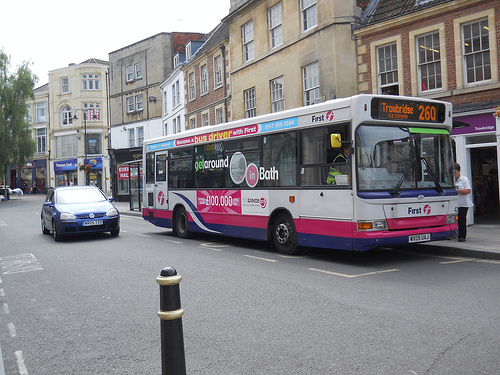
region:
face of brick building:
[365, 2, 497, 118]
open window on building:
[373, 40, 398, 97]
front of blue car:
[43, 183, 118, 240]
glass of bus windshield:
[357, 126, 454, 193]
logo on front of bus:
[406, 203, 431, 215]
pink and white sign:
[195, 188, 241, 213]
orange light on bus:
[356, 219, 372, 231]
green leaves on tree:
[0, 50, 40, 185]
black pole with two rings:
[158, 266, 185, 373]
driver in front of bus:
[323, 144, 355, 186]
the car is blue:
[30, 148, 237, 212]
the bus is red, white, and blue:
[121, 127, 493, 302]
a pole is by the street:
[120, 265, 222, 351]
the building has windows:
[194, 25, 328, 90]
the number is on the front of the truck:
[372, 88, 487, 118]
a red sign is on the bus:
[190, 192, 262, 213]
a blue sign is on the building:
[50, 160, 98, 170]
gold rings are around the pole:
[137, 258, 210, 361]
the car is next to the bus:
[27, 140, 395, 368]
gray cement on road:
[43, 267, 78, 288]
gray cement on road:
[227, 300, 267, 327]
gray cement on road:
[282, 335, 338, 360]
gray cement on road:
[239, 325, 321, 357]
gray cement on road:
[420, 330, 465, 365]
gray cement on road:
[440, 290, 475, 331]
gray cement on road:
[81, 255, 126, 315]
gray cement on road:
[121, 266, 151, 296]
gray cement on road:
[186, 260, 241, 300]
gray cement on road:
[236, 288, 297, 335]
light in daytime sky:
[0, 2, 232, 81]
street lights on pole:
[74, 107, 98, 182]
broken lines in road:
[0, 272, 30, 373]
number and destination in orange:
[378, 100, 438, 120]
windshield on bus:
[358, 129, 454, 196]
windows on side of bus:
[168, 120, 352, 190]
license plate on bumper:
[406, 232, 431, 244]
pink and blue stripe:
[145, 209, 355, 249]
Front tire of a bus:
[266, 220, 293, 242]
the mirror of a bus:
[378, 133, 399, 165]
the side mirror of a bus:
[328, 131, 342, 151]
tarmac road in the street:
[208, 268, 285, 322]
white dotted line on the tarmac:
[3, 300, 17, 338]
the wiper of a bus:
[400, 164, 409, 184]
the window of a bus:
[323, 142, 333, 160]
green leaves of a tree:
[12, 113, 27, 135]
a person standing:
[457, 167, 472, 212]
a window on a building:
[128, 98, 136, 113]